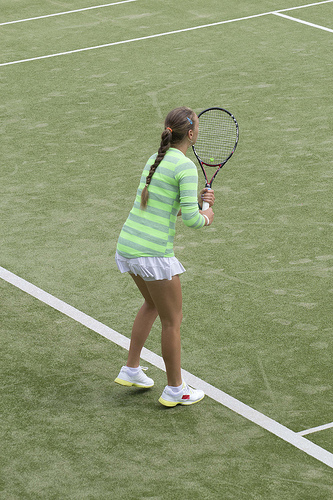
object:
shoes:
[156, 382, 274, 408]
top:
[117, 107, 215, 263]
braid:
[127, 130, 174, 204]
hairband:
[162, 124, 174, 133]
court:
[0, 2, 332, 500]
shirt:
[116, 146, 204, 258]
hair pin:
[185, 114, 193, 126]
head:
[161, 101, 200, 149]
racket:
[186, 100, 242, 217]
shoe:
[112, 365, 156, 390]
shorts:
[115, 253, 186, 282]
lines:
[5, 8, 186, 55]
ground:
[12, 79, 134, 179]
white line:
[20, 39, 131, 59]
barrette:
[183, 110, 195, 133]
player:
[113, 105, 214, 406]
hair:
[134, 101, 192, 206]